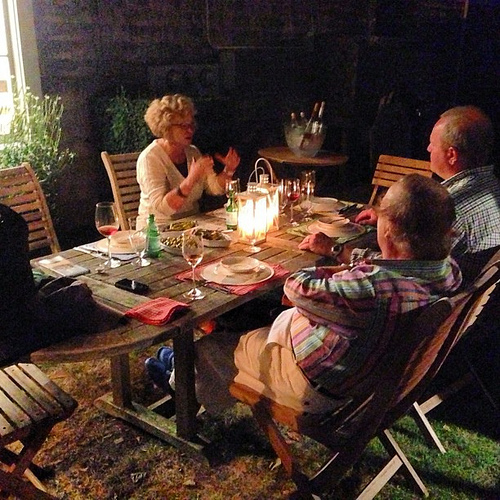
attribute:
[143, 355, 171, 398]
shoe — blue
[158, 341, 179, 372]
shoe — blue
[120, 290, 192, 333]
napkin — red, unused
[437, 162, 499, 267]
shirt — blue, white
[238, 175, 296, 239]
glass — wine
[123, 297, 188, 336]
napkin — red, cloth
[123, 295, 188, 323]
napkin — folded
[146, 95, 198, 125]
hair — blonde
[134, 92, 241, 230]
woman — gesturing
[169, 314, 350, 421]
pants — khaki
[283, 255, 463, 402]
shirt — plaid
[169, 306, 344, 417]
pants — tan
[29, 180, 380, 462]
table — outdoor